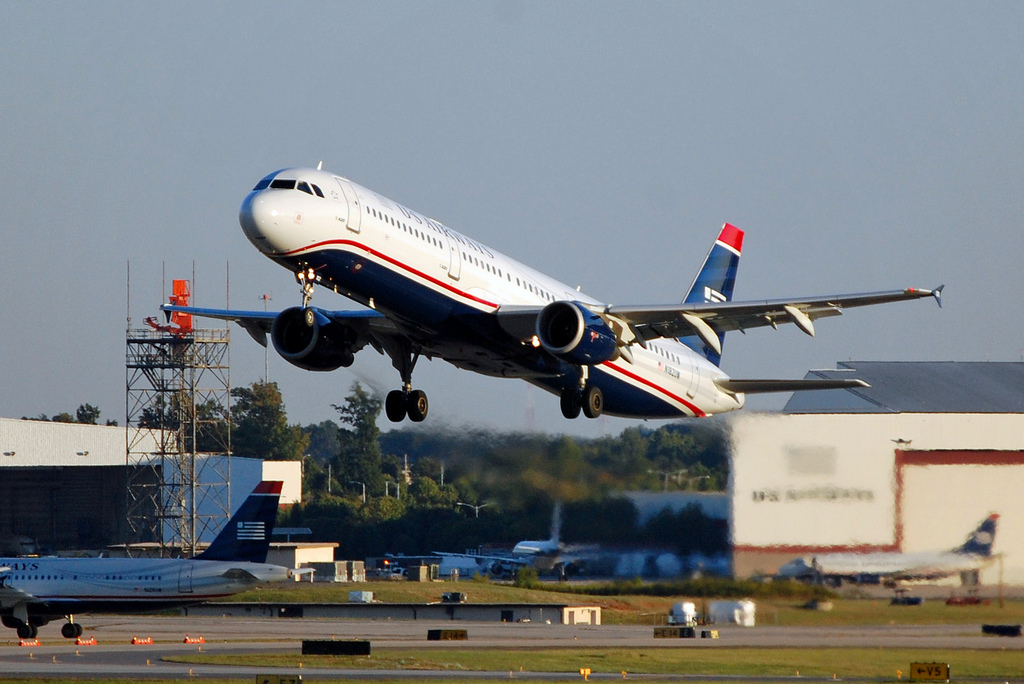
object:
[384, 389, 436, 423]
wheel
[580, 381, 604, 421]
wheels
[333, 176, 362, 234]
doors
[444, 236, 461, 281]
doors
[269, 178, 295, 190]
window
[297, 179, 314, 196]
window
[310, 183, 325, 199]
window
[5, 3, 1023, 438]
sky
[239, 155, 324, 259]
nose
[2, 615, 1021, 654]
runway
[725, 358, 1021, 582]
building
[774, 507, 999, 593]
plane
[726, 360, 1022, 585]
hangar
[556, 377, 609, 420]
wheel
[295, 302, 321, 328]
wheel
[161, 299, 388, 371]
wing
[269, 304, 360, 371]
engine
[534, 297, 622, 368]
engine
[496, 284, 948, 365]
wing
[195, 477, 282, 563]
tail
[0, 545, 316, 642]
plane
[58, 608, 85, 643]
wheel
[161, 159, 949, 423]
airplane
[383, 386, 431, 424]
landing gear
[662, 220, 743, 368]
tail